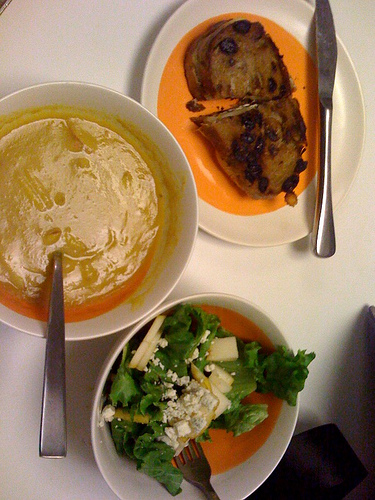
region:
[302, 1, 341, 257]
knife on edge of plate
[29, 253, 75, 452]
handle of silverware sticking out of bowl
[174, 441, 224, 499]
fork in small white bowl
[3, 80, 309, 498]
two white bowls on the table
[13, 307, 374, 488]
shadows on the white table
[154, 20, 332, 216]
orange sauce on white plate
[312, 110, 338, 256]
handle of the knife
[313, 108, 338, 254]
light glare on the knife handle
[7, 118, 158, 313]
yellow and orange liquid inbowl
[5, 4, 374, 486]
white table plate and bowls are on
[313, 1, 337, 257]
A silver butterknife on the side of a plate.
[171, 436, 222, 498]
A silver fork in the salad.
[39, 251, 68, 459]
The silver handle in the orange liquid.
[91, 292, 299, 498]
Oval white bowl with orange inside and salad.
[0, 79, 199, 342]
White round bowl with orange soup inside.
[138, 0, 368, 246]
Long white and orange plate with food on it.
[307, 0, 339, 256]
A butter knife silver in color.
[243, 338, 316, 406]
Piece of dark green salad coming out of the bowl.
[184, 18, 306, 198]
A sandwich in two parts on a plate.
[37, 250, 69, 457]
Long silver handle sticking out of orange liquid.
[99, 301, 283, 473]
orange and white salad bowl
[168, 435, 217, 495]
silver fork in salad bowl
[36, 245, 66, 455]
spoon in soup bowl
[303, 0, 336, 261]
knife on side of round dish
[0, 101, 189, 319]
orange soup in white bowl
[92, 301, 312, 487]
apple, feta, and lettuce salad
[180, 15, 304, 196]
brown bread with raisins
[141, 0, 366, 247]
orange dish with white edges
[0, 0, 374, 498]
bowls and plate on white table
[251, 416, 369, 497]
dark napkin next to salad bowl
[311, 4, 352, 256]
a sliver butter knife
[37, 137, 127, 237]
a golden soup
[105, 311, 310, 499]
a vegetable dinner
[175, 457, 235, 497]
a used fork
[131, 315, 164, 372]
a piece of tofu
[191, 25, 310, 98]
a lightly baked steak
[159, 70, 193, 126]
orange part of a plate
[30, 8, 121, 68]
that is a white table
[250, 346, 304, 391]
that is leafy green spinach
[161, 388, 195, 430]
that is blue cheese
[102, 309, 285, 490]
Salad in a bowl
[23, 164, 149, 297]
Soup in a bowl.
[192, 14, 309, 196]
Bread on a plate.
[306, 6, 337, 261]
Knife on a plate.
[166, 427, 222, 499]
Fork in a bowl.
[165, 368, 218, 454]
Cheese on a salad.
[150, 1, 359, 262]
An orange and white plate.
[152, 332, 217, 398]
Lettuce in a bowl.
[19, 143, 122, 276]
A creamy, yellow soup.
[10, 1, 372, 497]
Dinner on a white table.